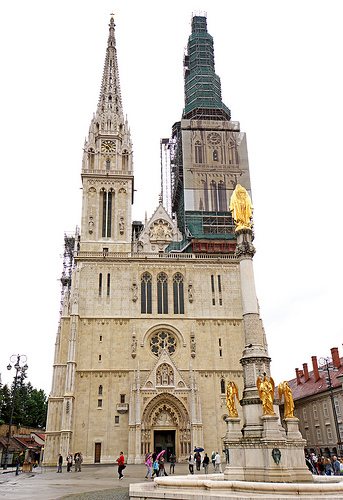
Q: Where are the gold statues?
A: Fountain.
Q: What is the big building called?
A: Cathedral.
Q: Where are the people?
A: Outside cathedral.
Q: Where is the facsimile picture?
A: Steeple.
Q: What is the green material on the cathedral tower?
A: Construction material.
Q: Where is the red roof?
A: Right of church.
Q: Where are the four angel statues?
A: Bottom of fountain.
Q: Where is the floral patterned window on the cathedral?
A: Above door.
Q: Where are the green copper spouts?
A: Fountain.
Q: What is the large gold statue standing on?
A: Pillar.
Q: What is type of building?
A: Cathedral.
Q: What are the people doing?
A: Walking.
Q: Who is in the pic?
A: Men and women.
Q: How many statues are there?
A: 4.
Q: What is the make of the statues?
A: Gold.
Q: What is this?
A: Temple.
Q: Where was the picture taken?
A: At a cathedral.